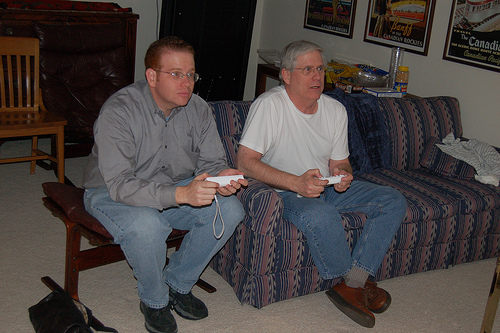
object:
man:
[83, 35, 249, 332]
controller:
[206, 175, 244, 189]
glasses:
[154, 69, 201, 82]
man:
[236, 41, 407, 330]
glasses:
[288, 65, 328, 75]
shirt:
[237, 85, 351, 198]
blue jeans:
[275, 179, 407, 280]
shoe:
[325, 276, 376, 328]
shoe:
[361, 276, 392, 314]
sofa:
[208, 96, 498, 309]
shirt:
[93, 81, 232, 211]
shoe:
[138, 297, 178, 332]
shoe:
[168, 279, 210, 320]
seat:
[41, 179, 217, 318]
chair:
[0, 35, 67, 183]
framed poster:
[303, 0, 357, 40]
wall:
[251, 1, 499, 148]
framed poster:
[360, 0, 437, 57]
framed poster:
[440, 0, 500, 73]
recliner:
[32, 22, 125, 160]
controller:
[317, 173, 348, 184]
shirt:
[435, 131, 500, 186]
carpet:
[0, 138, 499, 332]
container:
[393, 66, 409, 97]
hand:
[177, 172, 220, 205]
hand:
[216, 168, 248, 195]